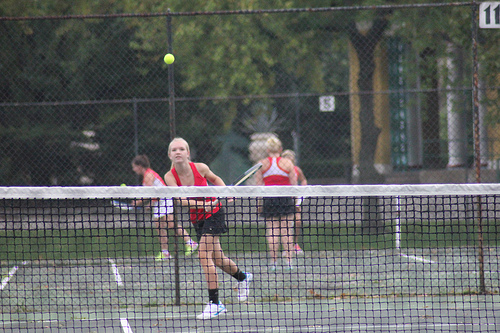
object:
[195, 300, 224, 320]
foot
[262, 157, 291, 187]
tank top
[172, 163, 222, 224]
tank top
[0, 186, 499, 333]
tennis net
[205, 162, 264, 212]
racket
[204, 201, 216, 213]
hand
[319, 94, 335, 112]
5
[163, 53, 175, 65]
ball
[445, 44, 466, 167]
column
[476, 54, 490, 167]
column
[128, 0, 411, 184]
tree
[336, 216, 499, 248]
ground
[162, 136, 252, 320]
girl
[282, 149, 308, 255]
people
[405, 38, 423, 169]
column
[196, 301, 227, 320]
shoe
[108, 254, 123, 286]
pole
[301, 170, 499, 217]
wall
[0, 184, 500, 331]
fence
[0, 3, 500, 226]
fence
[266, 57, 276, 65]
leaf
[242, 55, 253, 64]
leaf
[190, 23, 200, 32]
leaf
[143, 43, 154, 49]
leaf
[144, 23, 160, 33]
leaf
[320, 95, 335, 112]
tag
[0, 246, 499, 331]
court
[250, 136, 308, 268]
person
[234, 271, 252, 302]
foot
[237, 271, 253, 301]
shoe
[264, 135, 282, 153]
hair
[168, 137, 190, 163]
head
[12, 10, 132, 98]
air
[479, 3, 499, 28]
number 11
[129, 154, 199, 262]
person